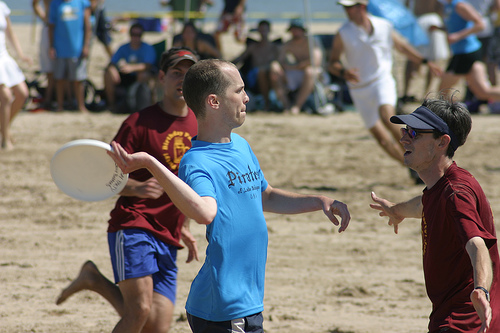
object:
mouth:
[240, 109, 247, 114]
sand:
[4, 105, 496, 330]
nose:
[242, 90, 249, 103]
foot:
[55, 259, 94, 305]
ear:
[207, 93, 221, 109]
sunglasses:
[399, 128, 439, 139]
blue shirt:
[176, 132, 269, 322]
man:
[105, 58, 351, 333]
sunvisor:
[389, 105, 451, 135]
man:
[368, 87, 500, 333]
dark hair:
[422, 87, 473, 158]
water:
[5, 2, 345, 22]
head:
[398, 88, 473, 172]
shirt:
[109, 103, 205, 251]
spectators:
[0, 0, 498, 160]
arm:
[147, 153, 218, 225]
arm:
[390, 194, 422, 218]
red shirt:
[421, 161, 500, 333]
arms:
[445, 191, 492, 288]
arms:
[247, 139, 321, 215]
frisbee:
[48, 139, 130, 201]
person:
[327, 0, 443, 187]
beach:
[245, 110, 395, 195]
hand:
[367, 191, 405, 236]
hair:
[182, 58, 240, 121]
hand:
[315, 195, 352, 234]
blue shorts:
[105, 227, 179, 306]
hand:
[105, 141, 146, 175]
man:
[54, 49, 200, 333]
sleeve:
[178, 152, 219, 202]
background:
[0, 0, 408, 30]